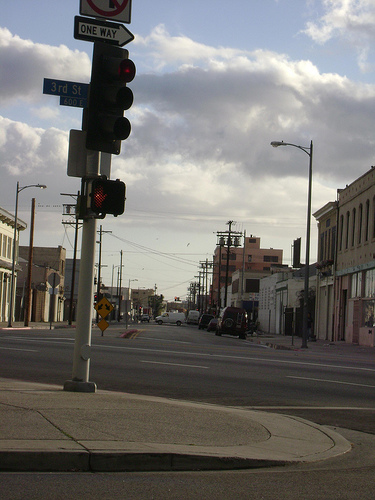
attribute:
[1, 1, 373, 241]
cloud — white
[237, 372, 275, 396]
street — black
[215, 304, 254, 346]
van — parked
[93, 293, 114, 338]
sign — yellow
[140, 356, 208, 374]
line — white